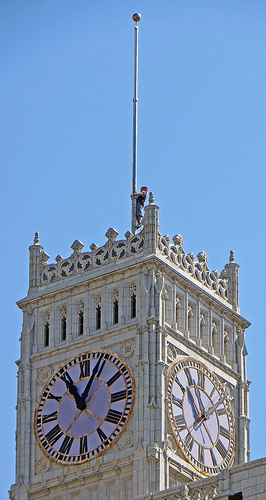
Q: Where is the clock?
A: On a building.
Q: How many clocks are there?
A: Two.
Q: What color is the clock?
A: White.